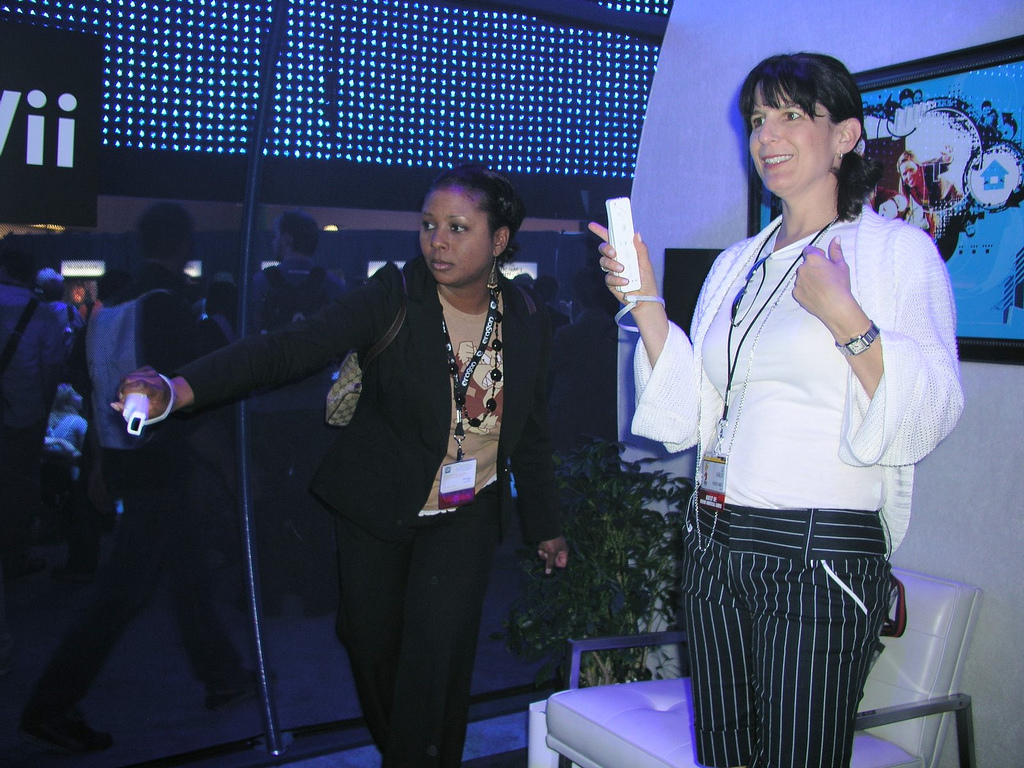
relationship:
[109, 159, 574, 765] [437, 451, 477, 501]
girl wearing id card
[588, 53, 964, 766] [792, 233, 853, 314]
woman has hand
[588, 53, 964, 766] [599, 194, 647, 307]
woman holding wii remote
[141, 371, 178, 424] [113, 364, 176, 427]
band on hand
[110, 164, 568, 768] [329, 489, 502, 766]
girl wearing pants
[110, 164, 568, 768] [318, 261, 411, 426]
girl carrying purse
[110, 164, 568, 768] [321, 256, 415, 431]
girl carrying purse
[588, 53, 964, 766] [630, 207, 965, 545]
woman wearing shirt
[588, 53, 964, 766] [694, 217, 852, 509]
woman wearing lanyard